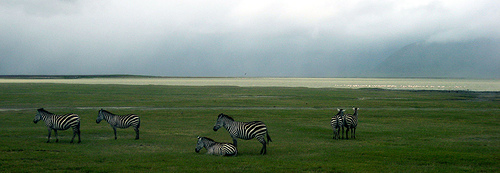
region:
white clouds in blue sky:
[6, 1, 46, 36]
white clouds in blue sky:
[21, 20, 59, 52]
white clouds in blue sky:
[82, 10, 137, 37]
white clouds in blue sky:
[98, 21, 146, 55]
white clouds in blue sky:
[162, 8, 226, 46]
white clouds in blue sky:
[211, 24, 281, 59]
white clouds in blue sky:
[301, 14, 358, 46]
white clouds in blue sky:
[347, 30, 424, 67]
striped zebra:
[211, 103, 268, 143]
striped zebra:
[103, 91, 143, 141]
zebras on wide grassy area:
[5, 87, 490, 167]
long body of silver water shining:
[0, 70, 497, 90]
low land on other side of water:
[0, 66, 230, 76]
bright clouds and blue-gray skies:
[5, 0, 495, 72]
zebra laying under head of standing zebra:
[190, 110, 277, 162]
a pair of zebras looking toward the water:
[320, 76, 365, 137]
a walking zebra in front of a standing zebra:
[25, 100, 142, 140]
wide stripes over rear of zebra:
[55, 110, 85, 130]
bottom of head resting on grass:
[190, 132, 205, 154]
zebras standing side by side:
[326, 98, 361, 138]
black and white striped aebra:
[31, 101, 90, 155]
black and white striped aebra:
[92, 100, 147, 149]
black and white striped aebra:
[189, 131, 237, 158]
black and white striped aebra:
[210, 102, 278, 147]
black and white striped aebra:
[309, 92, 370, 125]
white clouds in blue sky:
[11, 12, 86, 57]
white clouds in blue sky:
[110, 10, 177, 50]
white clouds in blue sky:
[189, 13, 255, 55]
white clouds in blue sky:
[266, 17, 333, 67]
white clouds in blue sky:
[348, 18, 411, 58]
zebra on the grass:
[191, 137, 234, 159]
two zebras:
[323, 102, 363, 143]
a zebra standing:
[208, 111, 277, 137]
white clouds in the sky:
[234, 5, 414, 42]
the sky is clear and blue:
[72, 46, 193, 78]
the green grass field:
[215, 84, 347, 109]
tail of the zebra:
[263, 126, 277, 142]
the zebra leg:
[107, 123, 123, 140]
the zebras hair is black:
[220, 113, 237, 122]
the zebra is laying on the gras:
[195, 134, 239, 162]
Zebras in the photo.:
[194, 112, 281, 161]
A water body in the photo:
[170, 72, 292, 86]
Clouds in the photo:
[242, 4, 364, 51]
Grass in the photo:
[297, 144, 378, 169]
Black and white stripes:
[238, 122, 268, 139]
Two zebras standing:
[25, 105, 143, 145]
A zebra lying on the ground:
[186, 128, 237, 164]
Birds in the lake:
[339, 80, 409, 89]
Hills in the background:
[393, 32, 475, 74]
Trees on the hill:
[386, 44, 458, 74]